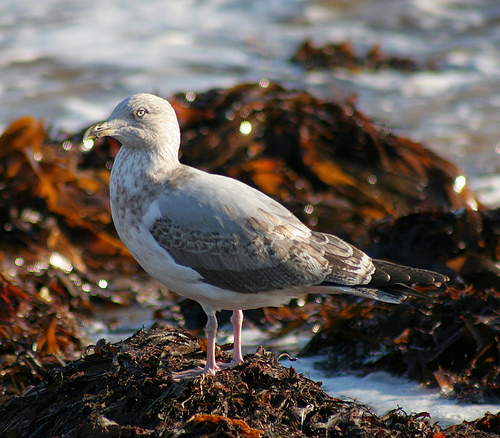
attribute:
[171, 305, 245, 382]
legs — pink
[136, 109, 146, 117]
eye — silver, yellow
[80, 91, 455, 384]
pigeon — gray, white, standing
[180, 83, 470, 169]
leaves — wet, orange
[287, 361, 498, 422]
foam — white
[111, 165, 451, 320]
feathers — white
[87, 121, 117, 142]
beak — yellow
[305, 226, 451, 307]
tail feathers — black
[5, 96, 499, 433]
surface — wet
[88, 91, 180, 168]
head — white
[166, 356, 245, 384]
feet — pink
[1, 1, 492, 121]
background — blurry